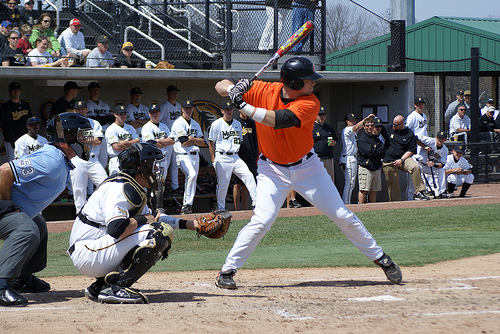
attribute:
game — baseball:
[15, 62, 497, 305]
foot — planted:
[214, 269, 247, 294]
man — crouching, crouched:
[75, 142, 210, 315]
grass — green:
[393, 208, 483, 254]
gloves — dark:
[224, 75, 258, 109]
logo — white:
[384, 257, 393, 265]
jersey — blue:
[11, 140, 74, 215]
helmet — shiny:
[280, 53, 321, 93]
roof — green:
[329, 20, 495, 71]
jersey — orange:
[240, 67, 327, 167]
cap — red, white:
[67, 14, 83, 27]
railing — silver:
[117, 17, 172, 67]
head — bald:
[391, 110, 405, 133]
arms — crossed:
[173, 131, 210, 154]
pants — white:
[224, 155, 385, 274]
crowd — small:
[3, 6, 131, 68]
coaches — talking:
[351, 111, 431, 200]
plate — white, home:
[341, 287, 414, 313]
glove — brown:
[192, 205, 231, 235]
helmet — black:
[274, 51, 317, 89]